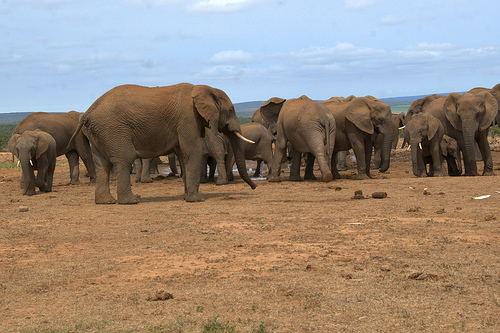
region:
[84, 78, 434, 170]
Elephants in a group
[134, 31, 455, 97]
The sky is clear and blue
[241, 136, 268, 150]
Turks on elephant.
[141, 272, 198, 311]
patches in the grass.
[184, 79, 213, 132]
A big ear on the elephant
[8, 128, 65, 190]
Small elephant with the big one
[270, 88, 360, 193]
the elephant is grey.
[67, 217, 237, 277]
Dirt in the grass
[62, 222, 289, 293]
The grass is brown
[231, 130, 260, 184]
Long trunk on the elephant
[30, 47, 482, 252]
many elephants on the ground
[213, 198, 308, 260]
dirt under the elephants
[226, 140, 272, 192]
trunk of the elephant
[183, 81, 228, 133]
ear of the elephant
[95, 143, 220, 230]
legs of the elephant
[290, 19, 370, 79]
clouds in the sky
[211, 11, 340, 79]
sky in the background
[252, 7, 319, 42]
blue sky above land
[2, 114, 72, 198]
baby elephant in the photo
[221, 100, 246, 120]
eye of the animal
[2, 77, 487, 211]
Several elephants all huddled together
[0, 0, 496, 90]
Sky with several clouds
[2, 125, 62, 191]
Baby elephant walking towards the camera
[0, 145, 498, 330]
Trampled ground under the feet of elephants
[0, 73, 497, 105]
Mountain range way off in the distance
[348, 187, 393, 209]
Animal poop on the ground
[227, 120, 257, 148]
One of many elephant tusks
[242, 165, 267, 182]
Part of lake behind elephant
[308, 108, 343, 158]
Elephants skinny tail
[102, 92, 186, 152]
Wrinkles on side of elephant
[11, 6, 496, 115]
a blue/greenish looking sky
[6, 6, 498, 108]
the sky is nice and calm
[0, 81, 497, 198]
elephants are around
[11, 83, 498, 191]
elephants are standing up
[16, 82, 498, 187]
the elephants are gray and brown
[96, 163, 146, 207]
the legs of an elephant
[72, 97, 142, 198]
the back part of an elephant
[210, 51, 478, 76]
clouds in the sky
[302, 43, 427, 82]
clouds look light blue in color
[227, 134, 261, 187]
the trunk of an elephant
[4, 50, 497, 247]
several elephants in the wild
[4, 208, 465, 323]
orange sandy soil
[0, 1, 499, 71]
a partly cloudy sky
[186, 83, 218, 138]
the ear of an elephant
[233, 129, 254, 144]
the tusk of an elephant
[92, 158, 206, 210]
the legs of an elephant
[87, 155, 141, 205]
the rear legs of an elephant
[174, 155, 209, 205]
the front legs of an elephant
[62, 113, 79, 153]
the tail of an elephant